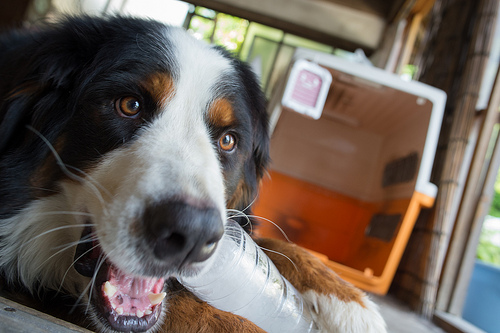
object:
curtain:
[414, 7, 498, 313]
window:
[431, 132, 498, 328]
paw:
[301, 265, 392, 332]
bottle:
[173, 219, 322, 331]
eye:
[218, 120, 243, 166]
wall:
[358, 4, 479, 309]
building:
[76, 0, 204, 44]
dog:
[4, 10, 389, 331]